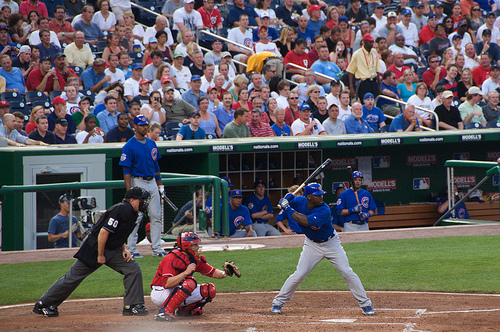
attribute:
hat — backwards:
[362, 87, 376, 99]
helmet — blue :
[303, 179, 325, 196]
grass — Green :
[27, 207, 498, 311]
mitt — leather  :
[221, 259, 241, 278]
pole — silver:
[375, 93, 439, 131]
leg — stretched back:
[33, 258, 88, 317]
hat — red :
[360, 33, 376, 42]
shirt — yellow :
[345, 45, 382, 81]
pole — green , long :
[12, 166, 234, 243]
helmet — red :
[164, 226, 203, 256]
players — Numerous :
[216, 173, 397, 238]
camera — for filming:
[69, 193, 99, 235]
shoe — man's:
[351, 292, 383, 322]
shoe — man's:
[256, 293, 291, 315]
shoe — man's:
[150, 309, 183, 324]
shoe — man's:
[111, 292, 148, 316]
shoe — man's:
[27, 292, 58, 315]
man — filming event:
[40, 183, 84, 240]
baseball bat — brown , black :
[283, 162, 337, 220]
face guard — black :
[136, 188, 156, 216]